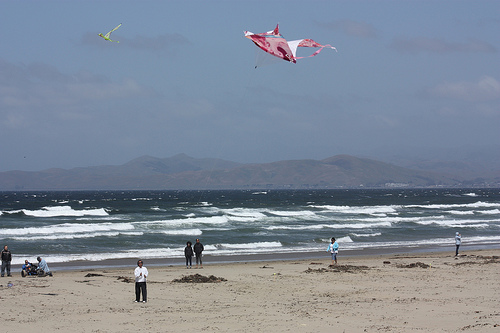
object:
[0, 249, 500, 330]
beach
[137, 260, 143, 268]
head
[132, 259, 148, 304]
man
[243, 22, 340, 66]
kite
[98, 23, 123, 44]
kite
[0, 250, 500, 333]
sand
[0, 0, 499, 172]
sky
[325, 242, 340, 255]
jacket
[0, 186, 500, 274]
ocean